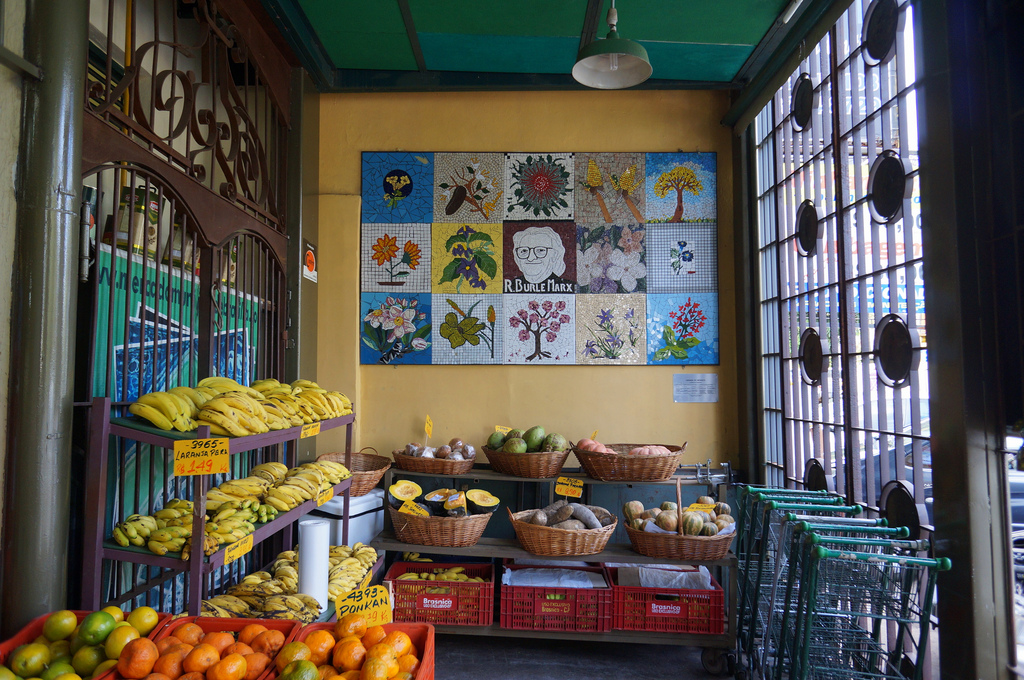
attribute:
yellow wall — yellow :
[302, 72, 776, 507]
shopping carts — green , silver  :
[691, 465, 959, 675]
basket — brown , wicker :
[624, 476, 743, 559]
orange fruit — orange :
[280, 597, 417, 675]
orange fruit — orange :
[136, 614, 283, 675]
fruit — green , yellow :
[25, 608, 164, 663]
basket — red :
[0, 597, 201, 669]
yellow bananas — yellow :
[103, 359, 369, 435]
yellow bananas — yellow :
[170, 525, 423, 632]